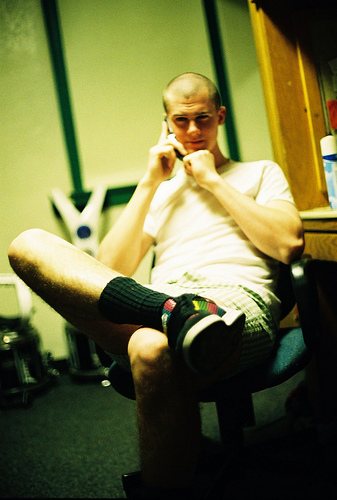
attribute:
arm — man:
[182, 148, 305, 265]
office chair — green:
[109, 247, 328, 494]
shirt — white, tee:
[140, 157, 295, 312]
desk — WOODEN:
[289, 207, 335, 336]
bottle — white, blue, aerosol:
[319, 134, 335, 210]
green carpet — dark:
[10, 369, 121, 450]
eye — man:
[174, 115, 186, 124]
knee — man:
[8, 227, 57, 278]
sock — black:
[102, 269, 174, 322]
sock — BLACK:
[95, 269, 184, 334]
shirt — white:
[136, 161, 314, 288]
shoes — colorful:
[153, 283, 255, 377]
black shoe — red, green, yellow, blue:
[163, 291, 248, 366]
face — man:
[163, 87, 220, 159]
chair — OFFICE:
[245, 265, 321, 497]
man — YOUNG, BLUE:
[9, 61, 303, 499]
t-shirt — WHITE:
[129, 161, 280, 279]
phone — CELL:
[158, 132, 186, 162]